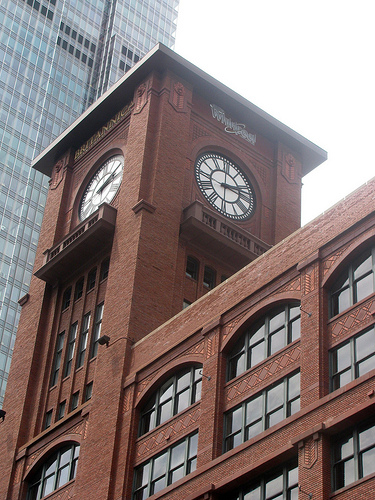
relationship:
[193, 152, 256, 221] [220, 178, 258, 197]
clock has a hand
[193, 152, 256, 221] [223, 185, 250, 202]
clock has a hand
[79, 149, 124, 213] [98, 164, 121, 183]
clock has a hand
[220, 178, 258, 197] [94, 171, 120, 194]
hand has a hand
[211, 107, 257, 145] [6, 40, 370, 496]
graffiti on building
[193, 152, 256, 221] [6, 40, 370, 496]
clock on building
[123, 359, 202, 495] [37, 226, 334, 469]
window on building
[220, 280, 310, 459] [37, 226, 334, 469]
window on building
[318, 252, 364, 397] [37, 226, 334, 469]
window on building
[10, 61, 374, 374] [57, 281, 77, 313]
building with windows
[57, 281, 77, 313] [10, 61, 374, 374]
windows on building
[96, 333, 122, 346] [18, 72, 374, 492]
camera on building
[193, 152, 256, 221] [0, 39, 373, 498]
clock on side of building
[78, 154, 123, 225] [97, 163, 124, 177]
clock has hands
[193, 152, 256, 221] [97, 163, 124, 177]
clock has hands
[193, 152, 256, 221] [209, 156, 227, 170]
clock has roman numeral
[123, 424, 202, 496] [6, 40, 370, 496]
window on side of building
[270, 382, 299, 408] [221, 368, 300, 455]
lines on window